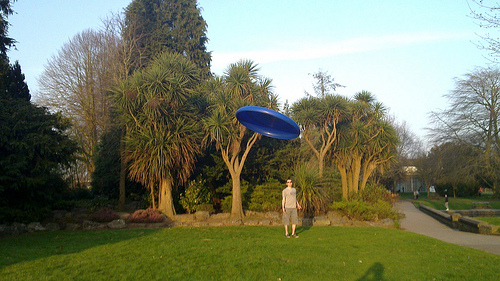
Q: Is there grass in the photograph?
A: Yes, there is grass.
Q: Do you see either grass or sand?
A: Yes, there is grass.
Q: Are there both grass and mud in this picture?
A: No, there is grass but no mud.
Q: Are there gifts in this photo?
A: No, there are no gifts.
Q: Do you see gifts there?
A: No, there are no gifts.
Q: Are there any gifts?
A: No, there are no gifts.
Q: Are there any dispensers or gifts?
A: No, there are no gifts or dispensers.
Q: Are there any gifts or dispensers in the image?
A: No, there are no gifts or dispensers.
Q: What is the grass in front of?
A: The grass is in front of the rock.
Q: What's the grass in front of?
A: The grass is in front of the rock.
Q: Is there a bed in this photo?
A: Yes, there is a bed.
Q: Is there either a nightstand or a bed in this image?
A: Yes, there is a bed.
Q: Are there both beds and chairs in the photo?
A: No, there is a bed but no chairs.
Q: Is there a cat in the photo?
A: No, there are no cats.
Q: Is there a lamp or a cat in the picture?
A: No, there are no cats or lamps.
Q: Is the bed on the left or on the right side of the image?
A: The bed is on the left of the image.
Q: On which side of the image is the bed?
A: The bed is on the left of the image.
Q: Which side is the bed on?
A: The bed is on the left of the image.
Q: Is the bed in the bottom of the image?
A: Yes, the bed is in the bottom of the image.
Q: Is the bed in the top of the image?
A: No, the bed is in the bottom of the image.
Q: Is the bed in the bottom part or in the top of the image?
A: The bed is in the bottom of the image.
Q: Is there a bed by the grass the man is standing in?
A: Yes, there is a bed by the grass.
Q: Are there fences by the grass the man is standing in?
A: No, there is a bed by the grass.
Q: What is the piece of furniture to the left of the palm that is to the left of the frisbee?
A: The piece of furniture is a bed.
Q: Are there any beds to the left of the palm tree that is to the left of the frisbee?
A: Yes, there is a bed to the left of the palm tree.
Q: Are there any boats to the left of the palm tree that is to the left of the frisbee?
A: No, there is a bed to the left of the palm tree.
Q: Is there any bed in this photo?
A: Yes, there is a bed.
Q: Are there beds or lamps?
A: Yes, there is a bed.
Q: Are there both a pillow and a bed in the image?
A: No, there is a bed but no pillows.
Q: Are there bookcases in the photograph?
A: No, there are no bookcases.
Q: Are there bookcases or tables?
A: No, there are no bookcases or tables.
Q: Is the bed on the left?
A: Yes, the bed is on the left of the image.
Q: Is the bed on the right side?
A: No, the bed is on the left of the image.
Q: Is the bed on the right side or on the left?
A: The bed is on the left of the image.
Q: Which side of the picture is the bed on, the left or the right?
A: The bed is on the left of the image.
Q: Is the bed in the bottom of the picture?
A: Yes, the bed is in the bottom of the image.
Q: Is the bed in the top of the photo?
A: No, the bed is in the bottom of the image.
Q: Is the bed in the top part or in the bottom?
A: The bed is in the bottom of the image.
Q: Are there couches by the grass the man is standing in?
A: No, there is a bed by the grass.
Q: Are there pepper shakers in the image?
A: No, there are no pepper shakers.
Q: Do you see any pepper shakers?
A: No, there are no pepper shakers.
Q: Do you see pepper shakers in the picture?
A: No, there are no pepper shakers.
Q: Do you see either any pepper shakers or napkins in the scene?
A: No, there are no pepper shakers or napkins.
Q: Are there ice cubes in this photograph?
A: No, there are no ice cubes.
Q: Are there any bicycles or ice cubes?
A: No, there are no ice cubes or bicycles.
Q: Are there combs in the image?
A: No, there are no combs.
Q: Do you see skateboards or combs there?
A: No, there are no combs or skateboards.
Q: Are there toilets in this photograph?
A: No, there are no toilets.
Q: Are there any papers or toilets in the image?
A: No, there are no toilets or papers.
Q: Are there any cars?
A: No, there are no cars.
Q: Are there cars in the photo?
A: No, there are no cars.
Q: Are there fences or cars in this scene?
A: No, there are no cars or fences.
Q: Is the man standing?
A: Yes, the man is standing.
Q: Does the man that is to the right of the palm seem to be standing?
A: Yes, the man is standing.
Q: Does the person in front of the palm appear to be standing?
A: Yes, the man is standing.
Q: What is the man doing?
A: The man is standing.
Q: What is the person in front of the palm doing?
A: The man is standing.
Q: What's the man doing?
A: The man is standing.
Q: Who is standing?
A: The man is standing.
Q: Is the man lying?
A: No, the man is standing.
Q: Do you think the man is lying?
A: No, the man is standing.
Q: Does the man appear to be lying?
A: No, the man is standing.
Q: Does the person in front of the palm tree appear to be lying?
A: No, the man is standing.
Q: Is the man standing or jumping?
A: The man is standing.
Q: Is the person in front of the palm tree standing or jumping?
A: The man is standing.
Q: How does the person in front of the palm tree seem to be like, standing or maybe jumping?
A: The man is standing.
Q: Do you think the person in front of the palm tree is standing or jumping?
A: The man is standing.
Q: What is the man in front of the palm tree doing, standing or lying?
A: The man is standing.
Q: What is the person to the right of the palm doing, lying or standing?
A: The man is standing.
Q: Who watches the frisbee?
A: The man watches the frisbee.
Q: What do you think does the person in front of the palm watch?
A: The man watches the frisbee.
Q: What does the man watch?
A: The man watches the frisbee.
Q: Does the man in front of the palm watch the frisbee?
A: Yes, the man watches the frisbee.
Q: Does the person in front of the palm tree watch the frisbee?
A: Yes, the man watches the frisbee.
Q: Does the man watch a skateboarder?
A: No, the man watches the frisbee.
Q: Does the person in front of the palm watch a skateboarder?
A: No, the man watches the frisbee.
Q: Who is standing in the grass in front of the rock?
A: The man is standing in the grass.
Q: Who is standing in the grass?
A: The man is standing in the grass.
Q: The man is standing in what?
A: The man is standing in the grass.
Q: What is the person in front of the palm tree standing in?
A: The man is standing in the grass.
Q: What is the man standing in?
A: The man is standing in the grass.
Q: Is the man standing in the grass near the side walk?
A: Yes, the man is standing in the grass.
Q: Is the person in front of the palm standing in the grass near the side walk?
A: Yes, the man is standing in the grass.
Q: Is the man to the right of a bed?
A: Yes, the man is to the right of a bed.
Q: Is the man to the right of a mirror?
A: No, the man is to the right of a bed.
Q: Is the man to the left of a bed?
A: No, the man is to the right of a bed.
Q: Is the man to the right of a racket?
A: No, the man is to the right of a palm tree.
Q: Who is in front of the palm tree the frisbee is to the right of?
A: The man is in front of the palm tree.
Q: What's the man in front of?
A: The man is in front of the palm.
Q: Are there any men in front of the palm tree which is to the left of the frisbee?
A: Yes, there is a man in front of the palm.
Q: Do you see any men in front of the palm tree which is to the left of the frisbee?
A: Yes, there is a man in front of the palm.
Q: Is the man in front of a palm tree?
A: Yes, the man is in front of a palm tree.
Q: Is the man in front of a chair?
A: No, the man is in front of a palm tree.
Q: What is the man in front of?
A: The man is in front of the palm tree.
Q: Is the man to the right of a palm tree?
A: Yes, the man is to the right of a palm tree.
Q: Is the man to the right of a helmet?
A: No, the man is to the right of a palm tree.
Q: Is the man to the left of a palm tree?
A: No, the man is to the right of a palm tree.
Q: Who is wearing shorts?
A: The man is wearing shorts.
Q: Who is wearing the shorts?
A: The man is wearing shorts.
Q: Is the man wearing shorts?
A: Yes, the man is wearing shorts.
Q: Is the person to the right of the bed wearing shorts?
A: Yes, the man is wearing shorts.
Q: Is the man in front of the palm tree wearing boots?
A: No, the man is wearing shorts.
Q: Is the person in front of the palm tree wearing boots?
A: No, the man is wearing shorts.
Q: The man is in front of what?
A: The man is in front of the palm tree.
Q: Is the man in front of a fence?
A: No, the man is in front of a palm tree.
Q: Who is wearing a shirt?
A: The man is wearing a shirt.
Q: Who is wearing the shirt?
A: The man is wearing a shirt.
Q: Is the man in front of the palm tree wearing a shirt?
A: Yes, the man is wearing a shirt.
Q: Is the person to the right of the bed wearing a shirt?
A: Yes, the man is wearing a shirt.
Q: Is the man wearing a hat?
A: No, the man is wearing a shirt.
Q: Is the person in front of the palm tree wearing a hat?
A: No, the man is wearing a shirt.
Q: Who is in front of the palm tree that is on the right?
A: The man is in front of the palm tree.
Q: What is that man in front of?
A: The man is in front of the palm tree.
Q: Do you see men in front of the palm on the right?
A: Yes, there is a man in front of the palm tree.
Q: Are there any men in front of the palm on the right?
A: Yes, there is a man in front of the palm tree.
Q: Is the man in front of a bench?
A: No, the man is in front of a palm tree.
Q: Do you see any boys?
A: No, there are no boys.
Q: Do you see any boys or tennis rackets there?
A: No, there are no boys or tennis rackets.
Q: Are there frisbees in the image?
A: Yes, there is a frisbee.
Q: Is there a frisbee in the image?
A: Yes, there is a frisbee.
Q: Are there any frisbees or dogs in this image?
A: Yes, there is a frisbee.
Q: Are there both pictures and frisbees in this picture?
A: No, there is a frisbee but no pictures.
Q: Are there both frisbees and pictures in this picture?
A: No, there is a frisbee but no pictures.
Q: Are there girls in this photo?
A: No, there are no girls.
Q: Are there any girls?
A: No, there are no girls.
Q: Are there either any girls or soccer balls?
A: No, there are no girls or soccer balls.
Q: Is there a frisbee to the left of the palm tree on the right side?
A: Yes, there is a frisbee to the left of the palm tree.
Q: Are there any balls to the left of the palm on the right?
A: No, there is a frisbee to the left of the palm.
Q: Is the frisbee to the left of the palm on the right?
A: Yes, the frisbee is to the left of the palm.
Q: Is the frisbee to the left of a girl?
A: No, the frisbee is to the left of the palm.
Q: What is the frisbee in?
A: The frisbee is in the air.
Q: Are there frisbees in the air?
A: Yes, there is a frisbee in the air.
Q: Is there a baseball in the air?
A: No, there is a frisbee in the air.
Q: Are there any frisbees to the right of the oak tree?
A: Yes, there is a frisbee to the right of the oak tree.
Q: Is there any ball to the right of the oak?
A: No, there is a frisbee to the right of the oak.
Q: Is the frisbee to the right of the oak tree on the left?
A: Yes, the frisbee is to the right of the oak tree.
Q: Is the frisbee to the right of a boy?
A: No, the frisbee is to the right of the oak tree.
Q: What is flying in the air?
A: The frisbee is flying in the air.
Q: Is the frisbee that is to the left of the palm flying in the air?
A: Yes, the frisbee is flying in the air.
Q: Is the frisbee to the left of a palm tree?
A: Yes, the frisbee is to the left of a palm tree.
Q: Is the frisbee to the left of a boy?
A: No, the frisbee is to the left of a palm tree.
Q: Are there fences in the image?
A: No, there are no fences.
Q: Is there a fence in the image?
A: No, there are no fences.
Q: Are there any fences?
A: No, there are no fences.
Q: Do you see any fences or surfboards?
A: No, there are no fences or surfboards.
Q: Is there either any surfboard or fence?
A: No, there are no fences or surfboards.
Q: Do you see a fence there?
A: No, there are no fences.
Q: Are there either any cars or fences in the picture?
A: No, there are no fences or cars.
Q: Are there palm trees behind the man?
A: Yes, there is a palm tree behind the man.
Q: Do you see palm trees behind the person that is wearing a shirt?
A: Yes, there is a palm tree behind the man.